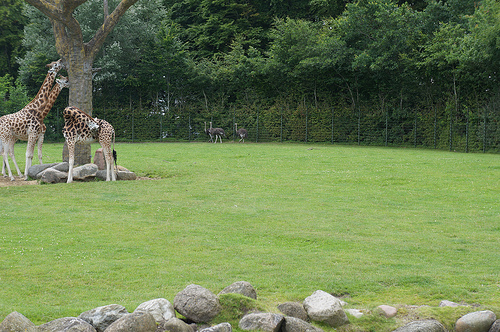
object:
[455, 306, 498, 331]
stone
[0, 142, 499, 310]
grass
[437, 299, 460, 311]
stone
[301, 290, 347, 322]
stone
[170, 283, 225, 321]
stone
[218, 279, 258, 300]
stone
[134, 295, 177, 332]
stone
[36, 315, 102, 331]
stone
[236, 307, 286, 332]
stone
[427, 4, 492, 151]
tree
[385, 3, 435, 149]
tree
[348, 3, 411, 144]
tree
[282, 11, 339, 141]
tree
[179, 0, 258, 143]
tree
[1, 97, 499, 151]
fence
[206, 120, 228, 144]
ostrich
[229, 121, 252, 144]
ostrich